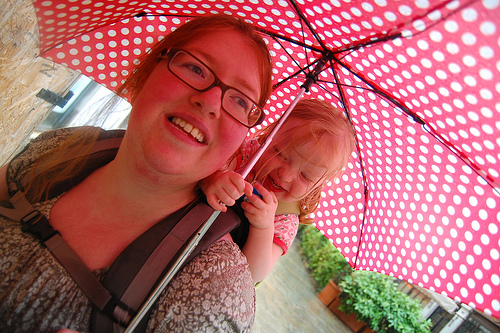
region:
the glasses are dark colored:
[128, 40, 285, 162]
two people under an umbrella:
[1, 0, 498, 325]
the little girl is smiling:
[234, 92, 363, 235]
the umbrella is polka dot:
[22, 0, 497, 317]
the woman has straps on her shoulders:
[3, 106, 258, 318]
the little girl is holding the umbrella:
[200, 5, 455, 275]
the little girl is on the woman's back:
[88, 6, 384, 328]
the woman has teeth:
[156, 94, 221, 172]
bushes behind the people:
[169, 100, 446, 331]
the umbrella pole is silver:
[92, 81, 388, 331]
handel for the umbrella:
[176, 82, 313, 319]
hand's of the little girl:
[188, 182, 291, 218]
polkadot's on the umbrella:
[392, 207, 454, 269]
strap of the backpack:
[88, 208, 218, 331]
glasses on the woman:
[140, 57, 297, 120]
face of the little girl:
[255, 136, 335, 206]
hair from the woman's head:
[59, 55, 154, 144]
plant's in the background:
[298, 299, 415, 331]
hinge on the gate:
[18, 83, 85, 113]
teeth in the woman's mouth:
[126, 118, 226, 148]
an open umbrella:
[25, 0, 494, 325]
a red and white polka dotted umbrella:
[31, 0, 498, 317]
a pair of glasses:
[163, 41, 265, 134]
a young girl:
[198, 97, 372, 274]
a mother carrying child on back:
[8, 6, 356, 329]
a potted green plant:
[316, 262, 433, 332]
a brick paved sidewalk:
[250, 236, 342, 328]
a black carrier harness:
[1, 119, 231, 330]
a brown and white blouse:
[1, 103, 248, 330]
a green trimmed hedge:
[297, 228, 347, 286]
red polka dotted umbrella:
[391, 43, 476, 284]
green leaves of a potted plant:
[346, 264, 419, 325]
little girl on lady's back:
[255, 82, 360, 247]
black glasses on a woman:
[160, 43, 274, 132]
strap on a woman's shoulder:
[135, 217, 187, 318]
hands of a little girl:
[203, 160, 282, 224]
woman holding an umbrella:
[9, 6, 287, 326]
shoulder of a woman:
[206, 239, 258, 309]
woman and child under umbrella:
[116, 12, 355, 223]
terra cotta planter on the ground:
[316, 275, 343, 310]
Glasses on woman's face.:
[169, 39, 322, 169]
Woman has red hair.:
[170, 8, 264, 72]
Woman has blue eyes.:
[180, 62, 296, 136]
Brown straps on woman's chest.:
[26, 168, 130, 302]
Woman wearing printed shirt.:
[6, 245, 61, 312]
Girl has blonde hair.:
[283, 100, 381, 192]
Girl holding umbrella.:
[208, 184, 279, 232]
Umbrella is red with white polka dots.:
[341, 87, 431, 226]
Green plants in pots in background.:
[346, 262, 378, 315]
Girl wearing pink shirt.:
[276, 212, 301, 263]